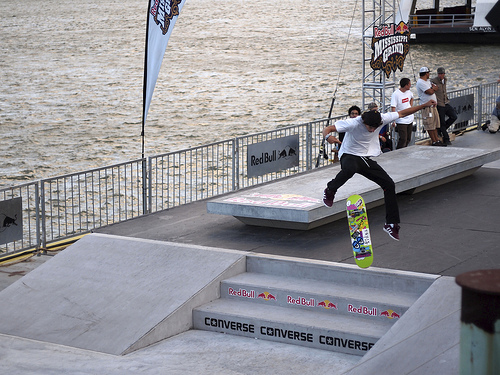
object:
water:
[3, 0, 487, 261]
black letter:
[301, 332, 306, 341]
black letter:
[294, 331, 300, 340]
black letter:
[260, 326, 266, 335]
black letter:
[204, 317, 210, 326]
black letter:
[224, 320, 231, 329]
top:
[455, 268, 498, 335]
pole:
[455, 267, 498, 371]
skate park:
[0, 192, 496, 375]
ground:
[398, 185, 434, 226]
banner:
[247, 133, 299, 178]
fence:
[0, 78, 499, 260]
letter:
[241, 323, 248, 333]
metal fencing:
[0, 77, 499, 264]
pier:
[0, 76, 500, 373]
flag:
[143, 0, 188, 121]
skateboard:
[345, 194, 372, 268]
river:
[0, 0, 497, 259]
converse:
[205, 317, 256, 334]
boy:
[322, 99, 439, 242]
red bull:
[250, 145, 297, 165]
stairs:
[189, 254, 435, 357]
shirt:
[333, 112, 400, 161]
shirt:
[390, 88, 414, 124]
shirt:
[417, 78, 438, 106]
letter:
[210, 318, 217, 327]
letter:
[218, 319, 223, 328]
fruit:
[133, 6, 185, 118]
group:
[327, 61, 464, 146]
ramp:
[3, 225, 268, 353]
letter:
[249, 324, 255, 334]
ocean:
[0, 2, 378, 254]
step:
[191, 299, 393, 359]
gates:
[2, 136, 237, 255]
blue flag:
[142, 0, 186, 120]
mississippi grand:
[369, 21, 411, 79]